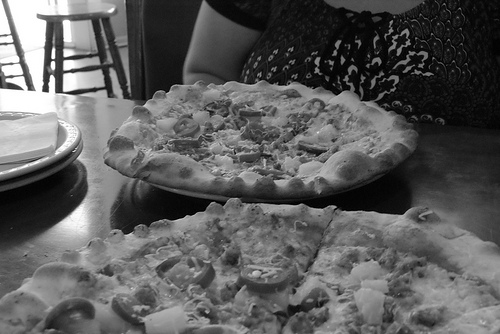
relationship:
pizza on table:
[102, 79, 419, 199] [0, 87, 499, 332]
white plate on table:
[0, 110, 84, 192] [0, 87, 499, 332]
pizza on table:
[105, 79, 416, 193] [0, 87, 499, 332]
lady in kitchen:
[180, 0, 500, 129] [4, 1, 484, 326]